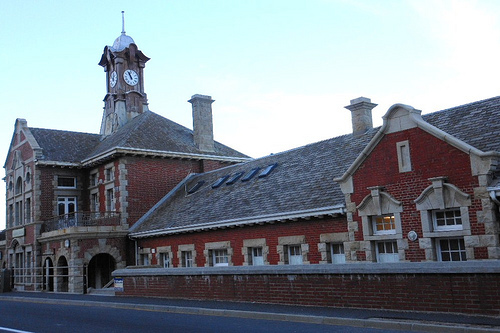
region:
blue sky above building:
[228, 14, 304, 57]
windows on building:
[363, 183, 470, 268]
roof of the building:
[274, 148, 330, 192]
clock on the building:
[116, 58, 156, 104]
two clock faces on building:
[99, 71, 147, 98]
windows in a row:
[176, 226, 322, 275]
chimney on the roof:
[178, 88, 231, 143]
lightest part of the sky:
[426, 20, 476, 63]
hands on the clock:
[120, 63, 142, 88]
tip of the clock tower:
[111, 8, 136, 30]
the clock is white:
[122, 63, 148, 93]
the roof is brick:
[222, 186, 348, 209]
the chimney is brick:
[189, 87, 226, 168]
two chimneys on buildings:
[177, 83, 383, 147]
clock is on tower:
[107, 35, 159, 130]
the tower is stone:
[102, 51, 138, 127]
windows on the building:
[372, 207, 459, 262]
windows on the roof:
[186, 174, 296, 189]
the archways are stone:
[37, 246, 124, 275]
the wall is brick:
[109, 262, 377, 312]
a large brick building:
[0, 7, 499, 314]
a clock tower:
[93, 7, 152, 110]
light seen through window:
[374, 212, 398, 237]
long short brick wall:
[110, 257, 499, 316]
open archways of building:
[43, 248, 123, 292]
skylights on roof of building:
[184, 160, 279, 195]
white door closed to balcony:
[46, 192, 120, 227]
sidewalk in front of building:
[13, 290, 498, 329]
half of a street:
[0, 298, 440, 331]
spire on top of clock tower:
[119, 9, 128, 37]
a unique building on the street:
[9, 57, 499, 318]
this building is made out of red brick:
[13, 92, 485, 304]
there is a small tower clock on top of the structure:
[63, 3, 218, 283]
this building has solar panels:
[168, 156, 308, 210]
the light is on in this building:
[357, 187, 413, 270]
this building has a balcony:
[35, 169, 128, 258]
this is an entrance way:
[37, 241, 137, 297]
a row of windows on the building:
[131, 236, 357, 271]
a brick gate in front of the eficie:
[112, 250, 497, 326]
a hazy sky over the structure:
[5, 9, 490, 166]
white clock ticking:
[118, 68, 139, 83]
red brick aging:
[335, 105, 480, 280]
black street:
[45, 295, 90, 325]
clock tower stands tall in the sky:
[90, 10, 150, 155]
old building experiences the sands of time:
[31, 132, 176, 197]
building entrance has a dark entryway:
[55, 225, 135, 310]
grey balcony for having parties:
[45, 170, 125, 240]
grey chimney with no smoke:
[175, 65, 220, 145]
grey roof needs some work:
[225, 165, 320, 195]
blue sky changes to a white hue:
[18, 5, 83, 90]